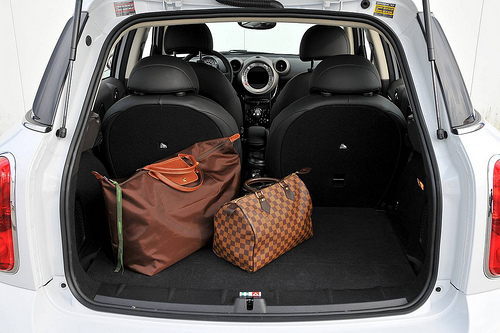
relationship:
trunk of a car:
[50, 4, 457, 320] [0, 0, 495, 330]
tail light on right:
[485, 153, 499, 278] [452, 1, 496, 328]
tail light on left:
[0, 152, 20, 278] [2, 3, 44, 333]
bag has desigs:
[209, 169, 321, 276] [241, 193, 303, 246]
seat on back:
[260, 49, 415, 211] [96, 59, 416, 298]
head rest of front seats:
[161, 23, 213, 61] [138, 23, 244, 123]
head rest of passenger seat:
[296, 21, 355, 61] [272, 25, 354, 105]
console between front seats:
[233, 50, 287, 128] [161, 26, 343, 81]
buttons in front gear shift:
[250, 105, 263, 122] [243, 125, 269, 148]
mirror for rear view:
[236, 19, 277, 35] [239, 19, 280, 32]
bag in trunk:
[209, 169, 321, 276] [50, 4, 457, 320]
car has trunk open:
[0, 0, 495, 330] [50, 4, 457, 320]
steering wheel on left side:
[184, 45, 236, 85] [115, 32, 195, 134]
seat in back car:
[260, 49, 415, 211] [0, 0, 495, 330]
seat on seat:
[260, 49, 415, 211] [260, 49, 415, 211]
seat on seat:
[105, 50, 244, 170] [260, 49, 415, 211]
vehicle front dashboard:
[0, 0, 495, 330] [222, 41, 296, 104]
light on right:
[485, 153, 499, 278] [452, 1, 496, 328]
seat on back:
[105, 50, 244, 170] [96, 59, 416, 298]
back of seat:
[103, 52, 243, 177] [272, 25, 354, 105]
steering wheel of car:
[184, 45, 236, 85] [0, 0, 495, 330]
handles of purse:
[141, 150, 211, 195] [90, 130, 247, 276]